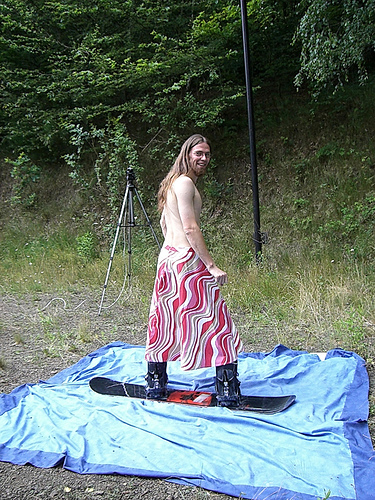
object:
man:
[145, 135, 243, 400]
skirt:
[145, 244, 244, 371]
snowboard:
[89, 377, 296, 414]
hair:
[155, 134, 211, 209]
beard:
[189, 163, 204, 175]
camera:
[126, 168, 134, 180]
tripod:
[98, 187, 161, 316]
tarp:
[0, 342, 374, 499]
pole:
[241, 0, 262, 265]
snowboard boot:
[145, 362, 168, 398]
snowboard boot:
[216, 365, 241, 407]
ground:
[0, 260, 373, 500]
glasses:
[194, 151, 211, 156]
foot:
[216, 360, 240, 406]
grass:
[0, 223, 375, 291]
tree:
[0, 0, 244, 156]